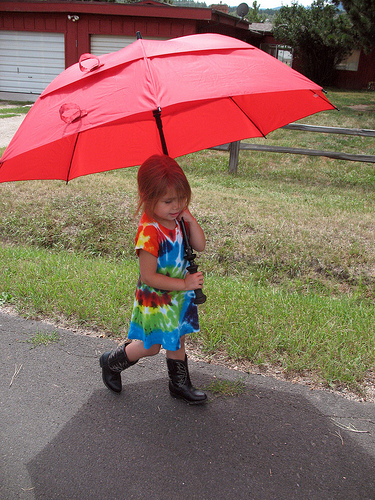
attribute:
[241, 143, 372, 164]
post — brown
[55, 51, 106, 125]
straps — red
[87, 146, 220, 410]
girl — little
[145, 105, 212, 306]
umbrella handle — black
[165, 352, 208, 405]
shoe — black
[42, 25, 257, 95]
cover — red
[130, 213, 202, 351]
girl's dress — little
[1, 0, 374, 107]
building — red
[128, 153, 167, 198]
hair — blonde